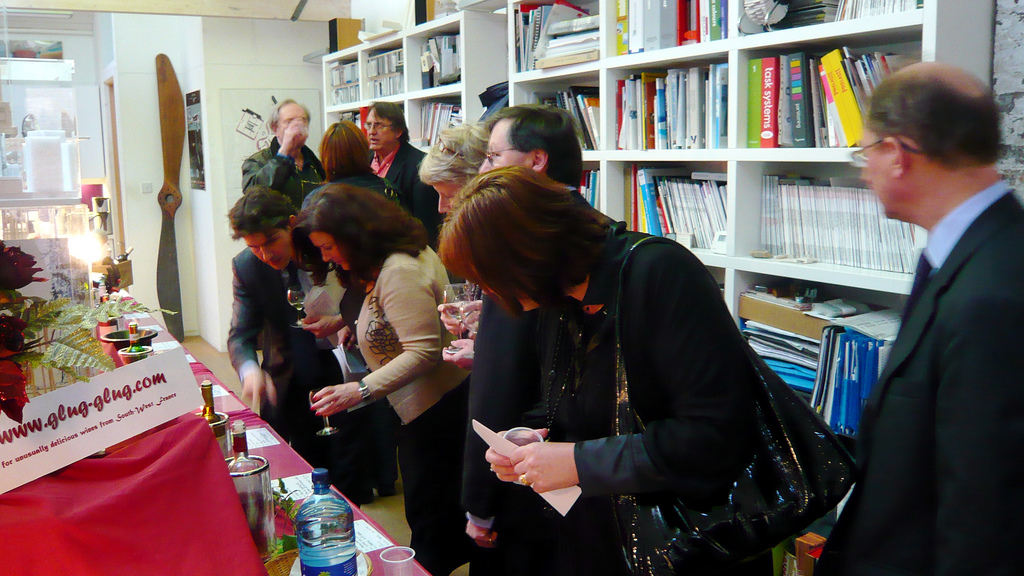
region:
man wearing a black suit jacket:
[810, 57, 1022, 571]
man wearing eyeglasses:
[816, 66, 1022, 573]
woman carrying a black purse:
[430, 171, 852, 573]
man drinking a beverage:
[236, 98, 326, 212]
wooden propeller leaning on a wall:
[141, 48, 196, 353]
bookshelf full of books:
[320, 38, 944, 430]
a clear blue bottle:
[289, 462, 365, 573]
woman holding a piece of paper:
[441, 165, 854, 570]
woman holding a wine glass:
[296, 180, 480, 573]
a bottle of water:
[279, 457, 359, 569]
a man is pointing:
[200, 174, 315, 435]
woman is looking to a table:
[277, 163, 459, 565]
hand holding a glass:
[295, 367, 350, 447]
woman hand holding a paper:
[387, 160, 844, 563]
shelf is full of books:
[586, 11, 853, 209]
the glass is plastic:
[371, 536, 420, 569]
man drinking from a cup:
[242, 81, 320, 189]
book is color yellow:
[812, 50, 873, 148]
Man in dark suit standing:
[815, 58, 1022, 568]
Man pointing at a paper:
[231, 184, 340, 489]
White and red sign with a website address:
[6, 341, 194, 493]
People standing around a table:
[214, 60, 1018, 572]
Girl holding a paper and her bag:
[439, 170, 854, 570]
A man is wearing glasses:
[833, 48, 1017, 238]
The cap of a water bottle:
[289, 450, 343, 495]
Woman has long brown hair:
[279, 165, 441, 295]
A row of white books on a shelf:
[734, 159, 934, 311]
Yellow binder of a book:
[807, 38, 868, 157]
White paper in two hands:
[453, 399, 594, 520]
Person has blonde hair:
[409, 106, 506, 217]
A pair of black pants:
[374, 361, 483, 562]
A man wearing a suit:
[787, 45, 1015, 562]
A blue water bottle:
[270, 444, 373, 569]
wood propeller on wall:
[148, 48, 191, 343]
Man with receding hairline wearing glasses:
[834, 58, 1019, 572]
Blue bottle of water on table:
[292, 468, 359, 571]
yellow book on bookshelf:
[818, 47, 860, 149]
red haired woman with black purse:
[437, 174, 855, 570]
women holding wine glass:
[296, 184, 468, 568]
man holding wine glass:
[226, 187, 299, 409]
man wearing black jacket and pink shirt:
[365, 99, 436, 220]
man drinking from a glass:
[242, 102, 320, 183]